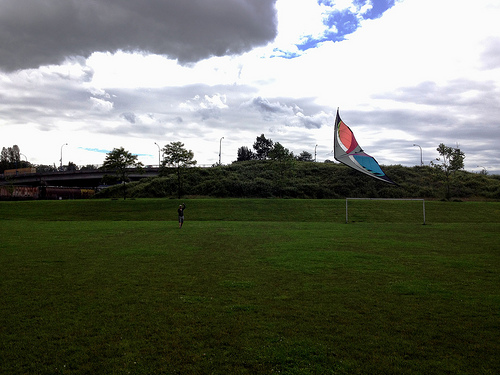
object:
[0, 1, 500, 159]
sky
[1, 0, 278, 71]
cloud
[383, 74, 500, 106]
cloud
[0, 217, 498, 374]
soccer field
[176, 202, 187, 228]
person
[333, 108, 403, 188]
kite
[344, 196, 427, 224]
goal net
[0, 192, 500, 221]
slope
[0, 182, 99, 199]
train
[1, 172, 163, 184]
bridge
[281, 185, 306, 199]
shrub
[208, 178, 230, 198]
shrub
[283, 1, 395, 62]
opening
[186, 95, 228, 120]
cloud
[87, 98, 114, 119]
cloud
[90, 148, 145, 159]
opening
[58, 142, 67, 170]
streetlight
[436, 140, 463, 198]
tree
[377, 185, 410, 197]
shrub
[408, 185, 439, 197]
shrub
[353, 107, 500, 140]
cloud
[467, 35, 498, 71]
cloud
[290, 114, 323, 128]
cloud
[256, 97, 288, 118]
cloud